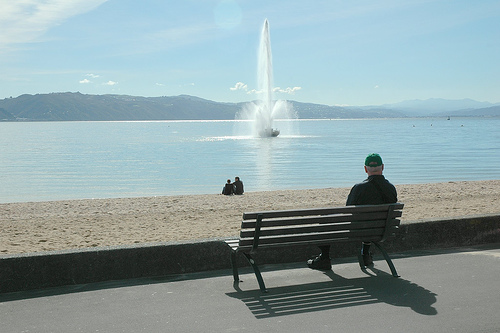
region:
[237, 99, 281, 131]
the mist of a fountain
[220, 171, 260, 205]
two people sitting in the sand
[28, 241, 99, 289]
the curb on the sidewalk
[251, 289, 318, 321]
the shadow of a bench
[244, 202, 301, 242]
the back of a park bench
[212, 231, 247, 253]
the seat of a bench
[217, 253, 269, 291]
the legs of a park bench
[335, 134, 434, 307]
This is a person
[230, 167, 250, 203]
This is a person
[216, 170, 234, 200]
This is a person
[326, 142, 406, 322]
This is a person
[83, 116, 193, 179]
Section of a lake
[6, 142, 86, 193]
Section of a lake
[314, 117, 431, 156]
Section of a lake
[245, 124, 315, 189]
Section of a lake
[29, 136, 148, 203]
Section of a lake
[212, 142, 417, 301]
a man sitting on the bench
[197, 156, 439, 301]
a man sitting on the bench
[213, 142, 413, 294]
a man sitting on the bench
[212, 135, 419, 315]
a man sitting on the bench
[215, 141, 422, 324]
a man sitting on the bench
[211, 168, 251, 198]
a couple sitting on the sand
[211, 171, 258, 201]
a couple sitting on the sand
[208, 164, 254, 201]
a couple sitting on the sand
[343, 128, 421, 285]
This is a person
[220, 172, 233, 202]
This is a person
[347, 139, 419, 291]
This is a person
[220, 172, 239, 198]
This is a person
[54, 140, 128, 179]
Section of an ocean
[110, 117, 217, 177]
Section of an ocean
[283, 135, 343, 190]
Section of an ocean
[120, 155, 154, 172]
Part of the water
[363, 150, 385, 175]
The head of the person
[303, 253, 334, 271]
The left foot of the person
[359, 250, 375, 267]
The right foot of the person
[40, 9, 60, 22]
Part of the cloud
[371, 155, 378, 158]
Part of the hat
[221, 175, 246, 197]
Two people sitting together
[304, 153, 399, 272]
white man sitting on bench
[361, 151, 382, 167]
small round green hat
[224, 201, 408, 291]
long wide wooden bench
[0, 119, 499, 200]
large wide open body of water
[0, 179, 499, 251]
large wide sandy beach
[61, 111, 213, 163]
a body of water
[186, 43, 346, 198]
a fountain in the water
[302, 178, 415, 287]
a bench on the sidealk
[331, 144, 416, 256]
a man sittin gon the bench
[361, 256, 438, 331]
a shadow on the sidewalk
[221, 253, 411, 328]
a shadow of a bench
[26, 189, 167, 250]
an area of sand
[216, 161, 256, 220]
a person sitting on the beach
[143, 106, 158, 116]
a mountain behind the water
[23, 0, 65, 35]
a white fluffy cloud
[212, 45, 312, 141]
this is a fountain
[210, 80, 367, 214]
the fountain is spouting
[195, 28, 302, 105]
the fountain is white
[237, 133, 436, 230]
the man is seated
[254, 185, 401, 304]
the bench is wooden